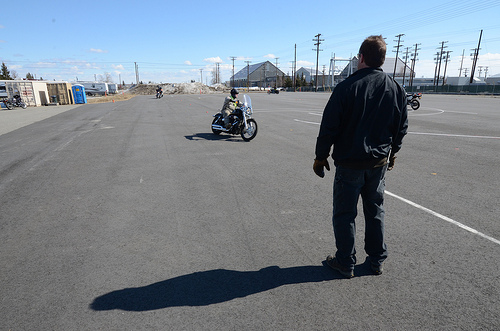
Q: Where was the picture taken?
A: On the street.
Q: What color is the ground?
A: Gray.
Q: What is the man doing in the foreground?
A: Watching others ride motorcycles.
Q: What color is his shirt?
A: Black.